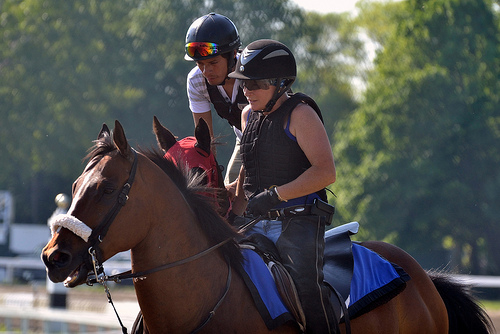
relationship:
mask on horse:
[172, 149, 191, 162] [5, 194, 418, 310]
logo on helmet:
[222, 42, 261, 59] [242, 43, 319, 65]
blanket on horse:
[366, 262, 376, 277] [5, 194, 418, 310]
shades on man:
[245, 85, 258, 91] [179, 8, 234, 112]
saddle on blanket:
[243, 252, 265, 272] [366, 262, 376, 277]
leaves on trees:
[10, 1, 107, 56] [399, 0, 440, 51]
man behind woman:
[179, 8, 234, 112] [244, 53, 306, 236]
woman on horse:
[244, 53, 306, 236] [5, 194, 418, 310]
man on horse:
[179, 8, 234, 112] [5, 194, 418, 310]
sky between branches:
[128, 68, 166, 100] [328, 3, 359, 16]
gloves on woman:
[231, 193, 284, 214] [244, 53, 306, 236]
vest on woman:
[252, 144, 275, 173] [244, 53, 306, 236]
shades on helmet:
[245, 85, 258, 91] [242, 43, 319, 65]